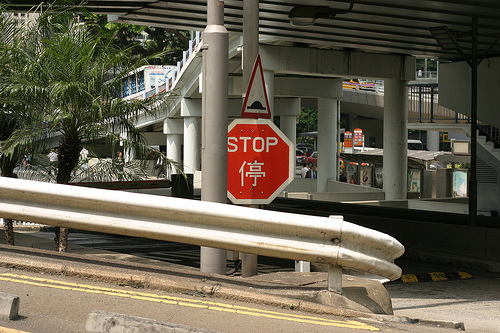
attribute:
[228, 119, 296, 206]
sign — red, octagon, orange, octangular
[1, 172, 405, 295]
rail — curved, bolted, metal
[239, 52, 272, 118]
trafficsign — triangular, tirangular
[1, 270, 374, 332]
line — yellow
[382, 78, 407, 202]
pillar — stone, concrete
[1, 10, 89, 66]
building — behind, red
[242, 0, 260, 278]
pole — grey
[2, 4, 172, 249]
tree — green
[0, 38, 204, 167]
bridge — metal, concrete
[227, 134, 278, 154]
letter — white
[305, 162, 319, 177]
man — behind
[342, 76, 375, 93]
taxi — yellow